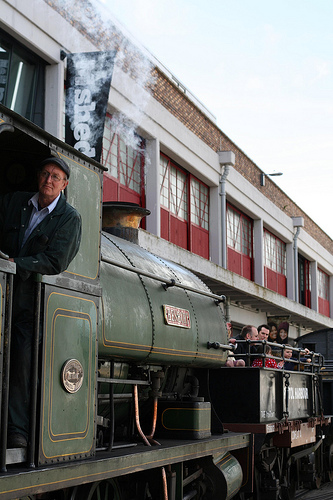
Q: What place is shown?
A: It is a station.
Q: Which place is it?
A: It is a station.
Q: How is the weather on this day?
A: It is cloudy.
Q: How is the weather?
A: It is cloudy.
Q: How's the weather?
A: It is cloudy.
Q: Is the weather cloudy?
A: Yes, it is cloudy.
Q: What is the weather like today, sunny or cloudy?
A: It is cloudy.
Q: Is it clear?
A: No, it is cloudy.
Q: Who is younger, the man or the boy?
A: The boy is younger than the man.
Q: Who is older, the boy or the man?
A: The man is older than the boy.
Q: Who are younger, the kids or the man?
A: The kids are younger than the man.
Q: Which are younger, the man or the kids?
A: The kids are younger than the man.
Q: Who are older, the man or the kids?
A: The man are older than the kids.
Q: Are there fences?
A: No, there are no fences.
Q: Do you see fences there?
A: No, there are no fences.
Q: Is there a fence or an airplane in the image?
A: No, there are no fences or airplanes.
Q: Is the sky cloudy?
A: Yes, the sky is cloudy.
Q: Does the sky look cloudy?
A: Yes, the sky is cloudy.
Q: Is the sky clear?
A: No, the sky is cloudy.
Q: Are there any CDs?
A: No, there are no cds.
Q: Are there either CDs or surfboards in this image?
A: No, there are no CDs or surfboards.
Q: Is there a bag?
A: No, there are no bags.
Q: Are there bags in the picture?
A: No, there are no bags.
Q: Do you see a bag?
A: No, there are no bags.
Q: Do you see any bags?
A: No, there are no bags.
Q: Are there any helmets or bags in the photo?
A: No, there are no bags or helmets.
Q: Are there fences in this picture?
A: No, there are no fences.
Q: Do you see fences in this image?
A: No, there are no fences.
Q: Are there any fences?
A: No, there are no fences.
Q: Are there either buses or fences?
A: No, there are no fences or buses.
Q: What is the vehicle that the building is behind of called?
A: The vehicle is a train.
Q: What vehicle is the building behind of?
A: The building is behind the train.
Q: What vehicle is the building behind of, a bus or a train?
A: The building is behind a train.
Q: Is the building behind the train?
A: Yes, the building is behind the train.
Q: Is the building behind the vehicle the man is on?
A: Yes, the building is behind the train.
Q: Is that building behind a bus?
A: No, the building is behind the train.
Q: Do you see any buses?
A: No, there are no buses.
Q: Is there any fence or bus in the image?
A: No, there are no buses or fences.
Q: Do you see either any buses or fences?
A: No, there are no buses or fences.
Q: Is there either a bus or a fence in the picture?
A: No, there are no buses or fences.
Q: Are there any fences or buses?
A: No, there are no buses or fences.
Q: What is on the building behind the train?
A: The sign is on the building.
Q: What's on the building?
A: The sign is on the building.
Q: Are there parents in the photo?
A: No, there are no parents.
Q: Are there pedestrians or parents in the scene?
A: No, there are no parents or pedestrians.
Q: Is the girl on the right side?
A: Yes, the girl is on the right of the image.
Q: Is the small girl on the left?
A: No, the girl is on the right of the image.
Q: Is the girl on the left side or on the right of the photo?
A: The girl is on the right of the image.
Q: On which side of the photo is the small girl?
A: The girl is on the right of the image.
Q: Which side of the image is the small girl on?
A: The girl is on the right of the image.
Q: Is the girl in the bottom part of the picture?
A: Yes, the girl is in the bottom of the image.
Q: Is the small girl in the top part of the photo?
A: No, the girl is in the bottom of the image.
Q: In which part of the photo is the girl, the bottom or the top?
A: The girl is in the bottom of the image.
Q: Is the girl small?
A: Yes, the girl is small.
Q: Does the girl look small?
A: Yes, the girl is small.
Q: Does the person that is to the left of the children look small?
A: Yes, the girl is small.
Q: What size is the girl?
A: The girl is small.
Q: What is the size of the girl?
A: The girl is small.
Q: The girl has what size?
A: The girl is small.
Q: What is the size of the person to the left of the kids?
A: The girl is small.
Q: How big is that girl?
A: The girl is small.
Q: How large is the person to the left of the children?
A: The girl is small.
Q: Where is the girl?
A: The girl is on the train.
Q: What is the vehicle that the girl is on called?
A: The vehicle is a train.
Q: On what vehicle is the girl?
A: The girl is on the train.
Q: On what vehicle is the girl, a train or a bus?
A: The girl is on a train.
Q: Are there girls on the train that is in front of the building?
A: Yes, there is a girl on the train.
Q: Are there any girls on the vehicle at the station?
A: Yes, there is a girl on the train.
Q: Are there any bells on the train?
A: No, there is a girl on the train.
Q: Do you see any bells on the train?
A: No, there is a girl on the train.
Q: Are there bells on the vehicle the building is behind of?
A: No, there is a girl on the train.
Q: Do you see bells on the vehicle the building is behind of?
A: No, there is a girl on the train.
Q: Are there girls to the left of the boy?
A: Yes, there is a girl to the left of the boy.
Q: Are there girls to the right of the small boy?
A: No, the girl is to the left of the boy.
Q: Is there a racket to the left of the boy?
A: No, there is a girl to the left of the boy.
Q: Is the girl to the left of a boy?
A: Yes, the girl is to the left of a boy.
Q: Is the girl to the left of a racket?
A: No, the girl is to the left of a boy.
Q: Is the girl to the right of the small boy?
A: No, the girl is to the left of the boy.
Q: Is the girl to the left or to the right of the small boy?
A: The girl is to the left of the boy.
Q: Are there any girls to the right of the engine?
A: Yes, there is a girl to the right of the engine.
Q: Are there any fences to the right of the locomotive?
A: No, there is a girl to the right of the locomotive.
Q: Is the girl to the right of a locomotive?
A: Yes, the girl is to the right of a locomotive.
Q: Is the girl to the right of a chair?
A: No, the girl is to the right of a locomotive.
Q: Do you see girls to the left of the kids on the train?
A: Yes, there is a girl to the left of the kids.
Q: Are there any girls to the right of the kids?
A: No, the girl is to the left of the kids.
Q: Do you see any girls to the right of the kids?
A: No, the girl is to the left of the kids.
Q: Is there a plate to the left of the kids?
A: No, there is a girl to the left of the kids.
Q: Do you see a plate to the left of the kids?
A: No, there is a girl to the left of the kids.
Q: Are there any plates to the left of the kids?
A: No, there is a girl to the left of the kids.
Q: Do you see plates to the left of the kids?
A: No, there is a girl to the left of the kids.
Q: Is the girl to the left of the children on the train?
A: Yes, the girl is to the left of the kids.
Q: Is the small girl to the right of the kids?
A: No, the girl is to the left of the kids.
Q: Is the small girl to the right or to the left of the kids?
A: The girl is to the left of the kids.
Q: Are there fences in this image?
A: No, there are no fences.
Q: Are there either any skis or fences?
A: No, there are no fences or skis.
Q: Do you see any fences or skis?
A: No, there are no fences or skis.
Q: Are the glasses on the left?
A: Yes, the glasses are on the left of the image.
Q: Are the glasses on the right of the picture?
A: No, the glasses are on the left of the image.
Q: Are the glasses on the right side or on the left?
A: The glasses are on the left of the image.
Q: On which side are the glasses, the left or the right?
A: The glasses are on the left of the image.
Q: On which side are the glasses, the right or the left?
A: The glasses are on the left of the image.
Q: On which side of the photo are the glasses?
A: The glasses are on the left of the image.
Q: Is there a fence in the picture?
A: No, there are no fences.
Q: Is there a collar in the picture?
A: Yes, there is a collar.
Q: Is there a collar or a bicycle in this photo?
A: Yes, there is a collar.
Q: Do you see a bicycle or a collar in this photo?
A: Yes, there is a collar.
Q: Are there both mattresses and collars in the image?
A: No, there is a collar but no mattresses.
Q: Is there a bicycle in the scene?
A: No, there are no bicycles.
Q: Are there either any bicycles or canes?
A: No, there are no bicycles or canes.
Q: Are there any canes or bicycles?
A: No, there are no bicycles or canes.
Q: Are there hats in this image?
A: Yes, there is a hat.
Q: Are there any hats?
A: Yes, there is a hat.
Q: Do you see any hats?
A: Yes, there is a hat.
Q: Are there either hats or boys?
A: Yes, there is a hat.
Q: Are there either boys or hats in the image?
A: Yes, there is a hat.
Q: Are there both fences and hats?
A: No, there is a hat but no fences.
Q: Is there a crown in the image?
A: No, there are no crowns.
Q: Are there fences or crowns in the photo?
A: No, there are no crowns or fences.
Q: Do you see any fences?
A: No, there are no fences.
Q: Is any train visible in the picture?
A: Yes, there is a train.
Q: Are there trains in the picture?
A: Yes, there is a train.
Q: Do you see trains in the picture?
A: Yes, there is a train.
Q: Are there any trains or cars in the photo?
A: Yes, there is a train.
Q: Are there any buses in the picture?
A: No, there are no buses.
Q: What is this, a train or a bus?
A: This is a train.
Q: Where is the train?
A: The train is at the station.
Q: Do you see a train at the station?
A: Yes, there is a train at the station.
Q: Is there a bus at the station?
A: No, there is a train at the station.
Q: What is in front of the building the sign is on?
A: The train is in front of the building.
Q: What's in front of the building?
A: The train is in front of the building.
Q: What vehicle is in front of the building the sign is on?
A: The vehicle is a train.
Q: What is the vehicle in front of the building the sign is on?
A: The vehicle is a train.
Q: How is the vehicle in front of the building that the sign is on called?
A: The vehicle is a train.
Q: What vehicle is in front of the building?
A: The vehicle is a train.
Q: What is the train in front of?
A: The train is in front of the building.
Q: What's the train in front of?
A: The train is in front of the building.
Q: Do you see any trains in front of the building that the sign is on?
A: Yes, there is a train in front of the building.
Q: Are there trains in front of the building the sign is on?
A: Yes, there is a train in front of the building.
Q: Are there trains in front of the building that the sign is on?
A: Yes, there is a train in front of the building.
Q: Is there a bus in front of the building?
A: No, there is a train in front of the building.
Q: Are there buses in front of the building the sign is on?
A: No, there is a train in front of the building.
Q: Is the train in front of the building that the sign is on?
A: Yes, the train is in front of the building.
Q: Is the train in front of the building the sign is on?
A: Yes, the train is in front of the building.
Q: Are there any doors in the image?
A: Yes, there is a door.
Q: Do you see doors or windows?
A: Yes, there is a door.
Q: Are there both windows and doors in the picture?
A: Yes, there are both a door and a window.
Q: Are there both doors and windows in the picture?
A: Yes, there are both a door and a window.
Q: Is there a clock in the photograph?
A: No, there are no clocks.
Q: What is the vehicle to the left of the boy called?
A: The vehicle is a locomotive.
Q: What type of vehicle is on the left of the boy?
A: The vehicle is a locomotive.